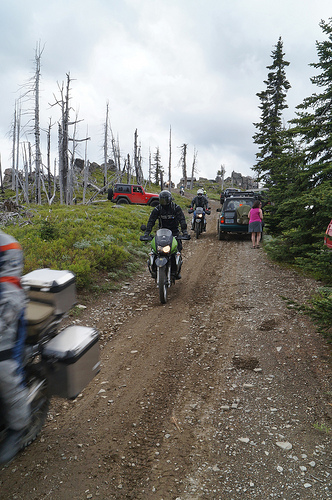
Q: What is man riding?
A: Bike.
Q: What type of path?
A: Dirt.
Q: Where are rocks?
A: In dirt.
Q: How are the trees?
A: Dead.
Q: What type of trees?
A: Pine.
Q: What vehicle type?
A: Motorcycle.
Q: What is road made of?
A: Dirt.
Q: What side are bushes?
A: Left.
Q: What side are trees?
A: Right.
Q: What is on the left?
A: Dead trees.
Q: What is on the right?
A: Pine trees.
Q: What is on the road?
A: Motor vehicles.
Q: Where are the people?
A: On a trail.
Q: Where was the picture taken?
A: On a trail.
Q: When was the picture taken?
A: Daytime.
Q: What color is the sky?
A: Gray.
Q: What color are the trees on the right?
A: Green.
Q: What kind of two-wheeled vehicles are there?
A: Motorcycles.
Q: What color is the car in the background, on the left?
A: Red.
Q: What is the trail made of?
A: Dirt.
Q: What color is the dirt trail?
A: Brown.